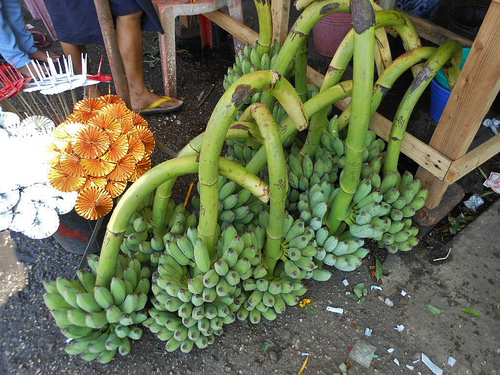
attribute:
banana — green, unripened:
[190, 235, 214, 273]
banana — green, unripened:
[173, 231, 197, 263]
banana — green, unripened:
[108, 273, 129, 306]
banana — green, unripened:
[90, 282, 116, 312]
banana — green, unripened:
[164, 237, 198, 271]